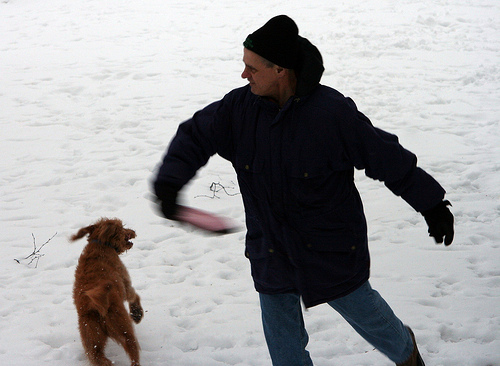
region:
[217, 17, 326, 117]
head of a person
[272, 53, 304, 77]
ear of a person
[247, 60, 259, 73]
eye of a person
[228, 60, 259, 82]
nose of a person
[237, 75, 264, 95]
mouth of a person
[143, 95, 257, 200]
arm of a person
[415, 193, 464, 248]
hand of a person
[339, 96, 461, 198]
arm of a person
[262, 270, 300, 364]
leg of a person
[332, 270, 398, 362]
leg of a person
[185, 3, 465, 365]
the man has a black coat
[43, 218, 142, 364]
the dog is running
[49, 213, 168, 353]
the dog is brown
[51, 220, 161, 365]
the dog is fuzzy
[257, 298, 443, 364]
the man has on jeans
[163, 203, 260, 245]
the dog is running after toy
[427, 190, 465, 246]
the man has gloves on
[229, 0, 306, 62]
the man has a black hat on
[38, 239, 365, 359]
they are playing in the snow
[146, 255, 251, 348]
the snow is white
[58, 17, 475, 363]
a man and a dog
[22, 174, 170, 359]
a medium brown dog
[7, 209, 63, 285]
a stick in the snow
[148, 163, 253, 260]
a frisbee in hand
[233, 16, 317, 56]
black hat on head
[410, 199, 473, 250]
black glove on hand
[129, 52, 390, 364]
black jacket and blue jeans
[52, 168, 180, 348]
the dog is running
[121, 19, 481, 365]
a man throwing a frisbee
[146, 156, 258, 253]
a red frisbee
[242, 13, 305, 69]
a black haton a man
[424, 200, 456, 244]
a black glove on a man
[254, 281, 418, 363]
blue jeans on a man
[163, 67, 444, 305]
a dark grey coat on a man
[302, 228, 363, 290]
a pocketo n a coat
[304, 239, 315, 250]
a button on a coat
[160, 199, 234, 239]
a red frisbee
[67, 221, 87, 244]
an ear of a dog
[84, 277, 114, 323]
the tale of a dog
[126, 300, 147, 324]
the underside of a dog's paw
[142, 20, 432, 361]
man holding a frisbee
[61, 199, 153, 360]
dog in the snow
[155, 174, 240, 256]
frisbee in a hand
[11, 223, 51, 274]
stick in the snow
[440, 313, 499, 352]
footprints in the snow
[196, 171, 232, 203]
sticks in the snow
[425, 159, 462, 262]
glove on man's hand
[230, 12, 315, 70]
hat on man's head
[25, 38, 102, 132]
footprints in the snow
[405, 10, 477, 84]
footprints in the snow